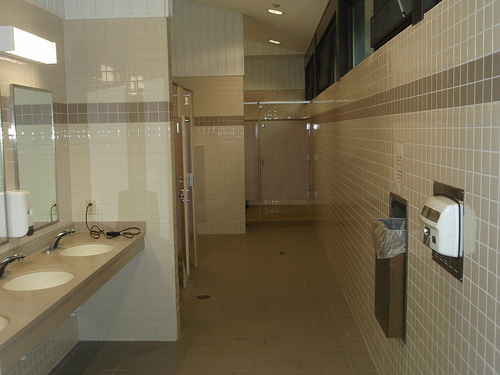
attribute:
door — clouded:
[257, 117, 313, 202]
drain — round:
[193, 291, 212, 300]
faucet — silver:
[43, 224, 81, 253]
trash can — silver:
[375, 218, 401, 345]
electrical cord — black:
[85, 224, 149, 244]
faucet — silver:
[48, 226, 79, 247]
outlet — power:
[81, 194, 99, 219]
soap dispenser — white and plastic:
[1, 175, 52, 260]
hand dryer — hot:
[423, 174, 490, 271]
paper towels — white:
[7, 190, 27, 239]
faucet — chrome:
[40, 225, 78, 256]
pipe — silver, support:
[243, 96, 310, 106]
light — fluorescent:
[2, 25, 67, 72]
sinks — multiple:
[6, 233, 118, 294]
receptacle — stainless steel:
[342, 199, 417, 349]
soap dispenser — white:
[4, 181, 36, 239]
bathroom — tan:
[1, 1, 496, 372]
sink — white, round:
[57, 241, 116, 257]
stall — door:
[227, 74, 332, 231]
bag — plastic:
[367, 214, 410, 344]